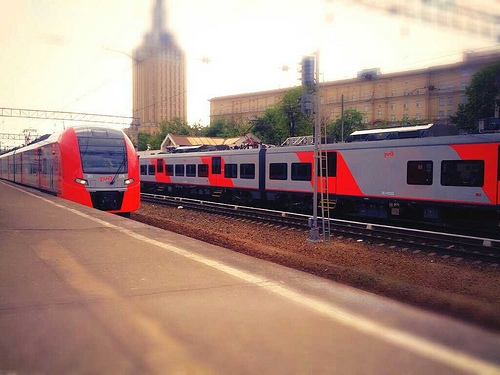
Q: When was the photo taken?
A: Daytime.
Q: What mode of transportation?
A: Train.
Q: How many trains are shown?
A: Two.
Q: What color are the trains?
A: Gray and orange.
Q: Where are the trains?
A: Tracks.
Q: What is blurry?
A: Background.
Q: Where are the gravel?
A: Beside the tracks.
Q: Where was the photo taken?
A: At a train station.